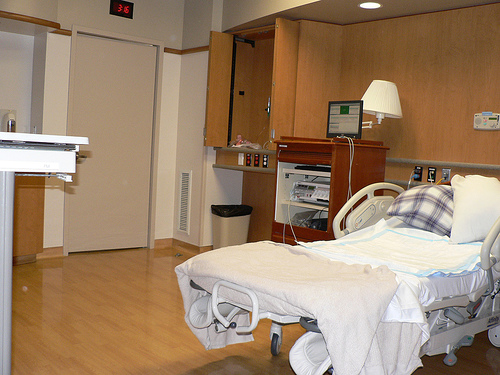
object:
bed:
[168, 172, 500, 375]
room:
[0, 1, 498, 373]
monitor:
[323, 98, 364, 139]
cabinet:
[268, 130, 395, 245]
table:
[0, 129, 90, 374]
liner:
[210, 202, 254, 219]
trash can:
[209, 203, 255, 252]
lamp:
[353, 77, 406, 128]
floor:
[0, 234, 500, 373]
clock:
[103, 0, 141, 24]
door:
[60, 26, 168, 258]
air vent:
[177, 166, 195, 236]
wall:
[173, 0, 229, 249]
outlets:
[411, 165, 425, 182]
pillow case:
[383, 181, 458, 237]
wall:
[296, 0, 499, 196]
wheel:
[265, 322, 287, 360]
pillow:
[446, 170, 500, 248]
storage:
[196, 17, 309, 174]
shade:
[356, 78, 405, 123]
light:
[356, 0, 386, 13]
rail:
[329, 180, 406, 241]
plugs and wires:
[439, 167, 455, 185]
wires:
[334, 131, 357, 236]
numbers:
[116, 3, 132, 15]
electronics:
[287, 178, 334, 208]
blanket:
[171, 238, 429, 374]